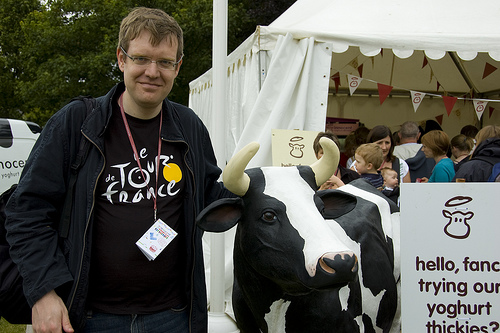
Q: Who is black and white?
A: A cow.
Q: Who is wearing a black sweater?
A: A man.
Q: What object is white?
A: The tent.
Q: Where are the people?
A: Inside the tent.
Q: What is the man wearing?
A: Glasses.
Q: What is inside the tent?
A: Red and white flags.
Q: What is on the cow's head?
A: Two white horns.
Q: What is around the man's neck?
A: A red lanyard.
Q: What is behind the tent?
A: Trees.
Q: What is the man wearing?
A: A jacket.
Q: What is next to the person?
A: A plastic cow.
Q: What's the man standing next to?
A: Statue.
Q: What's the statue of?
A: Cow.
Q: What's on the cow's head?
A: Horns.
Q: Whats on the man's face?
A: Glasses.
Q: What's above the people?
A: Tent.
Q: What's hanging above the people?
A: Triangle flags.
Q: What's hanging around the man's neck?
A: Lanyard.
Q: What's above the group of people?
A: White tent.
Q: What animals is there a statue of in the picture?
A: A cow.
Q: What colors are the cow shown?
A: Black and white.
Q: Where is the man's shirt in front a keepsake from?
A: The Tour de France.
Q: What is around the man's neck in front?
A: A badge.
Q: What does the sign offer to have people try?
A: Yogurt Thickies.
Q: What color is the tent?
A: White.